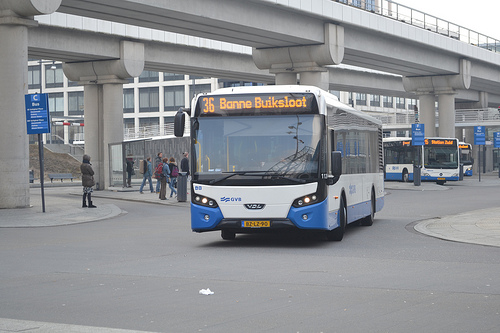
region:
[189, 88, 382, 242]
parked blue, white and black bus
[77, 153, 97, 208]
person standing on the sidewalks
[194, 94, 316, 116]
orange print on a black background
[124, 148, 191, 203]
people walking near the bus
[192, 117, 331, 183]
front windshield of the bus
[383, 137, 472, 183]
buses parked in the distance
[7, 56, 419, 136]
white building in the background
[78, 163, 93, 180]
woman wearing a black jacket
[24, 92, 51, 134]
blue and white sign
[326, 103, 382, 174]
passenger window on the left side of the bus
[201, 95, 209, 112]
orange number on bus sign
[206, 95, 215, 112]
orange number on bus sign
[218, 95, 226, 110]
orange letter on bus sign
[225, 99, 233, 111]
orange letter on bus sign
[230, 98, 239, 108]
orange letter on bus sign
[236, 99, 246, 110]
orange letter on bus sign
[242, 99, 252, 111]
orange letter on bus sign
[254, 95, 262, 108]
orange letter on bus sign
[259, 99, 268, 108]
orange letter on bus sign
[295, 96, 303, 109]
orange letter on bus sign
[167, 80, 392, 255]
A public transportation bus exiting a bus station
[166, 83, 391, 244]
A public transportation bus exiting a bus station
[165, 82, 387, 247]
A public transportation bus exiting a bus station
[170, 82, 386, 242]
A public transportation bus exiting a bus station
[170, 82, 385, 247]
A public transportation bus exiting a bus station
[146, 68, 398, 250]
this is a bus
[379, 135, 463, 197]
this is a bus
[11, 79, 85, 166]
this is a sign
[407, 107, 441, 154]
this is a sign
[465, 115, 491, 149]
this is a sign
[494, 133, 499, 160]
this is a sign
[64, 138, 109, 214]
this is a person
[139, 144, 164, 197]
this is a person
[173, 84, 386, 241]
White bus with blue stripe around bottom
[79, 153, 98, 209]
Person wearing jacket and standing on sidewalk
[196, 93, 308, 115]
Electronic sign on front of bus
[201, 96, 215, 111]
Number on the front of the bus.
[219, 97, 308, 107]
Writing on the front of the bus.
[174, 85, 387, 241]
Bus is on the street.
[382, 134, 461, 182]
Bus is on the street.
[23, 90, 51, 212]
Sign by the road.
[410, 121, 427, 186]
Sign by the road.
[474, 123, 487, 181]
Sign by the road.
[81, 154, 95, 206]
Person standing beside the road.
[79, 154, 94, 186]
Person wearing a coat.